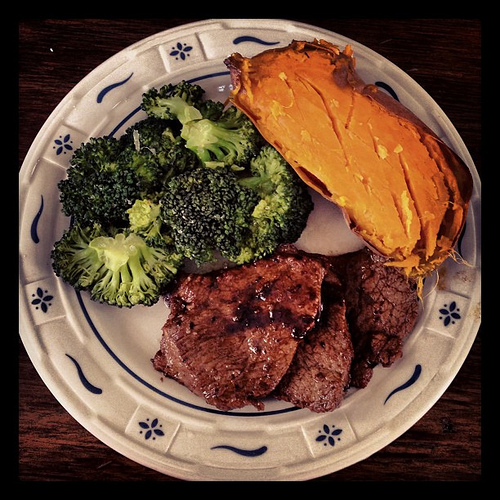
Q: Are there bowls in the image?
A: No, there are no bowls.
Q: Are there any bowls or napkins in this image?
A: No, there are no bowls or napkins.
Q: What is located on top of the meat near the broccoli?
A: The gravy is on top of the meat.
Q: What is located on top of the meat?
A: The gravy is on top of the meat.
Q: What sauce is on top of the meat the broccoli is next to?
A: The sauce is gravy.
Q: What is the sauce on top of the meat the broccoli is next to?
A: The sauce is gravy.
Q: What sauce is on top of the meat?
A: The sauce is gravy.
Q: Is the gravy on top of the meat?
A: Yes, the gravy is on top of the meat.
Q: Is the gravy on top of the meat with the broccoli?
A: Yes, the gravy is on top of the meat.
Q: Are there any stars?
A: Yes, there is a star.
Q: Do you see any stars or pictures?
A: Yes, there is a star.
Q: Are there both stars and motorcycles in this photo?
A: No, there is a star but no motorcycles.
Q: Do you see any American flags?
A: No, there are no American flags.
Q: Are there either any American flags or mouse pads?
A: No, there are no American flags or mouse pads.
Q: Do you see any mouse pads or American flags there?
A: No, there are no American flags or mouse pads.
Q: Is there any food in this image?
A: Yes, there is food.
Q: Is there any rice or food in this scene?
A: Yes, there is food.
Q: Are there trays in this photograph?
A: No, there are no trays.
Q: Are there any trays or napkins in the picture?
A: No, there are no trays or napkins.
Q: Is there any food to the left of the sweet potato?
A: Yes, there is food to the left of the sweet potato.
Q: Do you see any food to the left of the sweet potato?
A: Yes, there is food to the left of the sweet potato.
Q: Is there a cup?
A: No, there are no cups.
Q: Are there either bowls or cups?
A: No, there are no cups or bowls.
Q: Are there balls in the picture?
A: No, there are no balls.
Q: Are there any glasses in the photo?
A: No, there are no glasses.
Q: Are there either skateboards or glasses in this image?
A: No, there are no glasses or skateboards.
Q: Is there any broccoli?
A: Yes, there is broccoli.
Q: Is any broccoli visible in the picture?
A: Yes, there is broccoli.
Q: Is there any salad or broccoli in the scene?
A: Yes, there is broccoli.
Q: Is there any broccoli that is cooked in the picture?
A: Yes, there is cooked broccoli.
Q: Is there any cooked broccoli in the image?
A: Yes, there is cooked broccoli.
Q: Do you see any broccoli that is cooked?
A: Yes, there is broccoli that is cooked.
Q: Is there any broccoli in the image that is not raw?
A: Yes, there is cooked broccoli.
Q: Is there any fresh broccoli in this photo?
A: Yes, there is fresh broccoli.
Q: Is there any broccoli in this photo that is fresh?
A: Yes, there is broccoli that is fresh.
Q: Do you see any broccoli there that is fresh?
A: Yes, there is broccoli that is fresh.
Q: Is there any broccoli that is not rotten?
A: Yes, there is fresh broccoli.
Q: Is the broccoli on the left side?
A: Yes, the broccoli is on the left of the image.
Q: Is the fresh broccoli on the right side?
A: No, the broccoli is on the left of the image.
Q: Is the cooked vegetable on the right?
A: No, the broccoli is on the left of the image.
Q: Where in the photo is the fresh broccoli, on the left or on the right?
A: The broccoli is on the left of the image.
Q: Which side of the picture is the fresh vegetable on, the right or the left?
A: The broccoli is on the left of the image.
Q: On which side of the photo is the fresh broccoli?
A: The broccoli is on the left of the image.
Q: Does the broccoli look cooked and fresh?
A: Yes, the broccoli is cooked and fresh.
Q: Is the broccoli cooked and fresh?
A: Yes, the broccoli is cooked and fresh.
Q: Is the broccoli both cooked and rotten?
A: No, the broccoli is cooked but fresh.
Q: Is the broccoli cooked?
A: Yes, the broccoli is cooked.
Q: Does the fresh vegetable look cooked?
A: Yes, the broccoli is cooked.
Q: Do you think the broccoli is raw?
A: No, the broccoli is cooked.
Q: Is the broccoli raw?
A: No, the broccoli is cooked.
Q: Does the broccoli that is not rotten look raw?
A: No, the broccoli is cooked.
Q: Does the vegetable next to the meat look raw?
A: No, the broccoli is cooked.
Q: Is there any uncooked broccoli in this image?
A: No, there is broccoli but it is cooked.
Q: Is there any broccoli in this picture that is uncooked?
A: No, there is broccoli but it is cooked.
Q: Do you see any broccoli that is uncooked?
A: No, there is broccoli but it is cooked.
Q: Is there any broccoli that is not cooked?
A: No, there is broccoli but it is cooked.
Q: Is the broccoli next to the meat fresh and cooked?
A: Yes, the broccoli is fresh and cooked.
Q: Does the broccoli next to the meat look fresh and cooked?
A: Yes, the broccoli is fresh and cooked.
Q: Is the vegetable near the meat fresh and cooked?
A: Yes, the broccoli is fresh and cooked.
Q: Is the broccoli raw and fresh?
A: No, the broccoli is fresh but cooked.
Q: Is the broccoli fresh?
A: Yes, the broccoli is fresh.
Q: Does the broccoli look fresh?
A: Yes, the broccoli is fresh.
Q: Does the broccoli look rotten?
A: No, the broccoli is fresh.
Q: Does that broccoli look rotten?
A: No, the broccoli is fresh.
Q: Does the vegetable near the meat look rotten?
A: No, the broccoli is fresh.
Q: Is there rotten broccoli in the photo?
A: No, there is broccoli but it is fresh.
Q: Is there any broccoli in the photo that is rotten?
A: No, there is broccoli but it is fresh.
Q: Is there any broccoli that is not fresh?
A: No, there is broccoli but it is fresh.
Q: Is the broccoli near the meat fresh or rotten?
A: The broccoli is fresh.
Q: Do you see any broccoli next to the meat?
A: Yes, there is broccoli next to the meat.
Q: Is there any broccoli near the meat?
A: Yes, there is broccoli near the meat.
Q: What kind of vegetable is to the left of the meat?
A: The vegetable is broccoli.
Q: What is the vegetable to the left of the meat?
A: The vegetable is broccoli.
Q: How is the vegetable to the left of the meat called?
A: The vegetable is broccoli.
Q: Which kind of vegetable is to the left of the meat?
A: The vegetable is broccoli.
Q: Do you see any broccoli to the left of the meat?
A: Yes, there is broccoli to the left of the meat.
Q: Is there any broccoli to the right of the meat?
A: No, the broccoli is to the left of the meat.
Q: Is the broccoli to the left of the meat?
A: Yes, the broccoli is to the left of the meat.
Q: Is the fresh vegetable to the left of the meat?
A: Yes, the broccoli is to the left of the meat.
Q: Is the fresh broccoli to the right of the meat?
A: No, the broccoli is to the left of the meat.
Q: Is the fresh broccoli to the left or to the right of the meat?
A: The broccoli is to the left of the meat.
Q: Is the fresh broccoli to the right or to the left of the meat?
A: The broccoli is to the left of the meat.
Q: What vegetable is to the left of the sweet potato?
A: The vegetable is broccoli.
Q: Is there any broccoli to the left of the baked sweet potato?
A: Yes, there is broccoli to the left of the sweet potato.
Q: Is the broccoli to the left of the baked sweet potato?
A: Yes, the broccoli is to the left of the sweet potato.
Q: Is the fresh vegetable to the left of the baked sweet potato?
A: Yes, the broccoli is to the left of the sweet potato.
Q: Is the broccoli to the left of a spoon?
A: No, the broccoli is to the left of the sweet potato.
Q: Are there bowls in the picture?
A: No, there are no bowls.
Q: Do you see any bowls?
A: No, there are no bowls.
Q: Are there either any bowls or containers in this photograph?
A: No, there are no bowls or containers.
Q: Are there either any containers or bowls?
A: No, there are no bowls or containers.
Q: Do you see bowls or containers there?
A: No, there are no bowls or containers.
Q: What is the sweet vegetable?
A: The vegetable is a sweet potato.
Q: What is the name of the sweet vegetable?
A: The vegetable is a sweet potato.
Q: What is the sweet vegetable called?
A: The vegetable is a sweet potato.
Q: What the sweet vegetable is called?
A: The vegetable is a sweet potato.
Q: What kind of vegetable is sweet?
A: The vegetable is a sweet potato.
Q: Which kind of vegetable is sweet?
A: The vegetable is a sweet potato.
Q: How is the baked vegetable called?
A: The vegetable is a sweet potato.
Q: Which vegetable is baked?
A: The vegetable is a sweet potato.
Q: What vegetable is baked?
A: The vegetable is a sweet potato.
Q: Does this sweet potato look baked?
A: Yes, the sweet potato is baked.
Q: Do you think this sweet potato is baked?
A: Yes, the sweet potato is baked.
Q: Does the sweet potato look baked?
A: Yes, the sweet potato is baked.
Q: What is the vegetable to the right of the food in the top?
A: The vegetable is a sweet potato.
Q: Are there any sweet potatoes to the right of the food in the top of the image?
A: Yes, there is a sweet potato to the right of the food.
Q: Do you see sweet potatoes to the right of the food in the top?
A: Yes, there is a sweet potato to the right of the food.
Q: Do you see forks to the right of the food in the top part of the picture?
A: No, there is a sweet potato to the right of the food.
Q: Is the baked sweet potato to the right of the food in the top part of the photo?
A: Yes, the sweet potato is to the right of the food.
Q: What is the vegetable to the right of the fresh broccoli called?
A: The vegetable is a sweet potato.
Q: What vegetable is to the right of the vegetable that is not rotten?
A: The vegetable is a sweet potato.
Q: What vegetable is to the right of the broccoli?
A: The vegetable is a sweet potato.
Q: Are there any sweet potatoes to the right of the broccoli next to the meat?
A: Yes, there is a sweet potato to the right of the broccoli.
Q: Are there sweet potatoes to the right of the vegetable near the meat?
A: Yes, there is a sweet potato to the right of the broccoli.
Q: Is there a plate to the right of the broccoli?
A: No, there is a sweet potato to the right of the broccoli.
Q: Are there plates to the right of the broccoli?
A: No, there is a sweet potato to the right of the broccoli.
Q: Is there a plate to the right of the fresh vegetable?
A: No, there is a sweet potato to the right of the broccoli.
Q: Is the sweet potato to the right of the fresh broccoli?
A: Yes, the sweet potato is to the right of the broccoli.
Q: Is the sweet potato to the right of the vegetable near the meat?
A: Yes, the sweet potato is to the right of the broccoli.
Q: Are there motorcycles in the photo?
A: No, there are no motorcycles.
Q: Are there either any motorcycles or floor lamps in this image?
A: No, there are no motorcycles or floor lamps.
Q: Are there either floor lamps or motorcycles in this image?
A: No, there are no motorcycles or floor lamps.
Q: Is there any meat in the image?
A: Yes, there is meat.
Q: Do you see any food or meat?
A: Yes, there is meat.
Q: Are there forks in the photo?
A: No, there are no forks.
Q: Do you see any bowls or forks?
A: No, there are no forks or bowls.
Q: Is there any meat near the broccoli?
A: Yes, there is meat near the broccoli.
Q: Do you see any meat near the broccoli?
A: Yes, there is meat near the broccoli.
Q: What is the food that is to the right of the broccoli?
A: The food is meat.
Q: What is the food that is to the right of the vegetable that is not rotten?
A: The food is meat.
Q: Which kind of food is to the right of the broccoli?
A: The food is meat.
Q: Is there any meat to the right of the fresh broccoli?
A: Yes, there is meat to the right of the broccoli.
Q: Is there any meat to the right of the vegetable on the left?
A: Yes, there is meat to the right of the broccoli.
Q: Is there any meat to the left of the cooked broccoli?
A: No, the meat is to the right of the broccoli.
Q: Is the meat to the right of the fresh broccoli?
A: Yes, the meat is to the right of the broccoli.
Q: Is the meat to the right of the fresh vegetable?
A: Yes, the meat is to the right of the broccoli.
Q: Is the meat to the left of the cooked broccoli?
A: No, the meat is to the right of the broccoli.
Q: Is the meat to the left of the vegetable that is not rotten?
A: No, the meat is to the right of the broccoli.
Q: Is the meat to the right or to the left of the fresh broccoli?
A: The meat is to the right of the broccoli.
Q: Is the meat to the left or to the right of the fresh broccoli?
A: The meat is to the right of the broccoli.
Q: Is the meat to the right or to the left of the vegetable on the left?
A: The meat is to the right of the broccoli.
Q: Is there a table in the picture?
A: Yes, there is a table.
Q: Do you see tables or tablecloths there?
A: Yes, there is a table.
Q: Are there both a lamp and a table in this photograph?
A: No, there is a table but no lamps.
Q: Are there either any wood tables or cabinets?
A: Yes, there is a wood table.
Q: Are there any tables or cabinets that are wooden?
A: Yes, the table is wooden.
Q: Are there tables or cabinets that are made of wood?
A: Yes, the table is made of wood.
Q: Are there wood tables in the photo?
A: Yes, there is a wood table.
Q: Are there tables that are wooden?
A: Yes, there is a table that is wooden.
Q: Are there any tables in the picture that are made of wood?
A: Yes, there is a table that is made of wood.